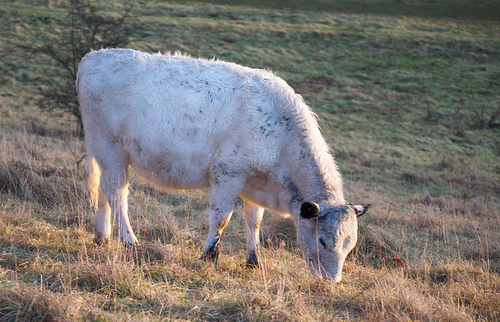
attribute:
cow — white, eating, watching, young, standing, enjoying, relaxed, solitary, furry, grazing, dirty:
[76, 47, 370, 283]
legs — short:
[93, 159, 266, 271]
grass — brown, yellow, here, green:
[1, 0, 500, 319]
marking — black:
[199, 237, 221, 265]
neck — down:
[269, 125, 347, 222]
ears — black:
[299, 199, 372, 219]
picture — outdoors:
[1, 1, 499, 322]